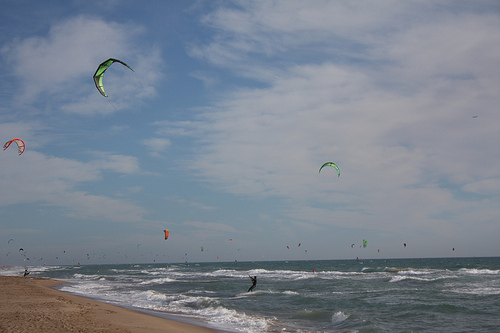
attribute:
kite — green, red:
[87, 53, 137, 98]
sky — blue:
[142, 20, 291, 168]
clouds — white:
[255, 67, 437, 138]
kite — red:
[2, 130, 34, 157]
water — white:
[25, 255, 500, 330]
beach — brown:
[5, 277, 198, 328]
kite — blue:
[320, 158, 345, 181]